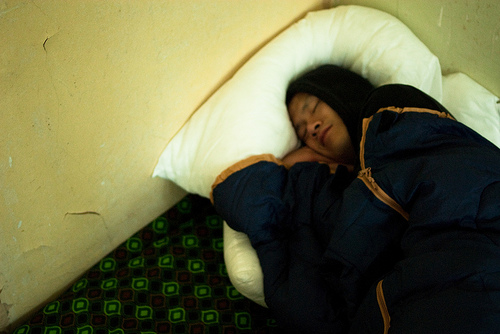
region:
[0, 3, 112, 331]
The wall is very battered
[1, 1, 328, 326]
The wall is yellow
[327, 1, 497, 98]
The wall has stains on it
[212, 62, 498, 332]
The woman is sleeping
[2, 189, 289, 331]
The carpet is green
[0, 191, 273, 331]
The carpet has a green pattern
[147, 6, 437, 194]
The woman's head is on a pillow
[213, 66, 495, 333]
The woman is sleeping on the floor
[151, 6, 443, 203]
The pillow is white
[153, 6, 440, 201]
The pillow is on the floor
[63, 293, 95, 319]
square black pattern with outer and inner yellow circles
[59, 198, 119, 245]
large hole in wall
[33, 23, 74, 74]
small hole in wall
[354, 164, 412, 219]
light tan strip on black coat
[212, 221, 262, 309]
portion of white fluffy pillow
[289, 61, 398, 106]
long, straight black hair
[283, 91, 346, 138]
girl laying on bed with her eyes closed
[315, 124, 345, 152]
light red lipstick on lips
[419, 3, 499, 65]
soil on light blue wall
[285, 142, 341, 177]
hand is curled up under girl's cheek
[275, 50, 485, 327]
a person asleep in a sleeping bag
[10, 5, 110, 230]
cracked plaster wall that is painted yellow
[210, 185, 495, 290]
zippered navy blue sleeping bag with a tan zipper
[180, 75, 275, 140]
a white pillow that looks comfortable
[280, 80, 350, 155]
a sleeping person's face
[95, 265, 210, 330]
green and black pattern on carpet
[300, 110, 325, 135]
a sleeping person's nose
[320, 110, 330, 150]
a sleeping person's mouth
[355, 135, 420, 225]
tan colored zipper closure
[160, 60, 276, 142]
a white pillow pressed into a wall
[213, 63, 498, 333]
a person lying on the ground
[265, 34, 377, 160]
person's head on a white pillow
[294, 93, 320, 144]
person's eyes are closed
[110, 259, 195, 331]
a diamond pattern on the ground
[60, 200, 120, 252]
a crack on the wall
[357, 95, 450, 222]
person wearing a blue robe with orange details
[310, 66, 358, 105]
person has dark hair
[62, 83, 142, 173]
wall is painted yellow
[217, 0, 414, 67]
pillow is touching the wall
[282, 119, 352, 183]
person's hand is next to their face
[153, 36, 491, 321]
a woman sleeping with a white pillow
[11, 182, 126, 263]
cracked and chipped paint on the wall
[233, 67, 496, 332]
woman sleeping in a sleeping bag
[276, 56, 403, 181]
woman smiling while asleep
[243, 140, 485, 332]
a zip up sleeping bag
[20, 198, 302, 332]
a weird green designed carpet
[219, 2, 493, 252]
a lady sleeping in a corner of a room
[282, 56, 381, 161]
a lady with dark hair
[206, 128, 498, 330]
a blue and brown sleeping bag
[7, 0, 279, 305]
a dirty tan colored wall